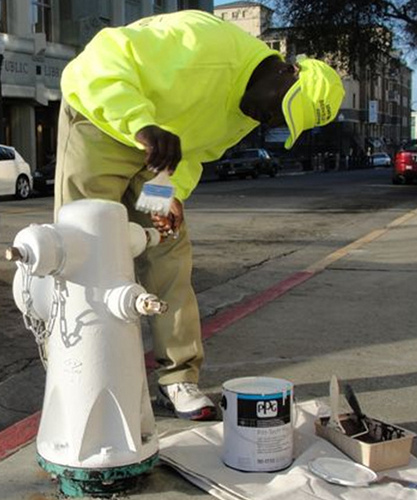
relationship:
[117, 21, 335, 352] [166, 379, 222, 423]
man has shoe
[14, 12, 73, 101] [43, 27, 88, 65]
building has window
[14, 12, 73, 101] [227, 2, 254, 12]
building has roof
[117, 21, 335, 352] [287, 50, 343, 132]
man has hat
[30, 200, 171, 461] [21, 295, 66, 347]
fire hydrand has chain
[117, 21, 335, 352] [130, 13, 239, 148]
man wearing jacket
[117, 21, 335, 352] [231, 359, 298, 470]
man next to can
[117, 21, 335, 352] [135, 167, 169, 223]
man holding paint brush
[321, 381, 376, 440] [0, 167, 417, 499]
untensils on street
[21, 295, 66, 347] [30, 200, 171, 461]
chain on fire hydrand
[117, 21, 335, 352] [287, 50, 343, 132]
man wearing hat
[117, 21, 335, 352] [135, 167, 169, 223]
man has paint brush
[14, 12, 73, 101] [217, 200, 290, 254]
building on street